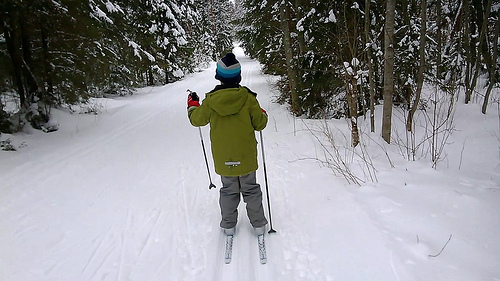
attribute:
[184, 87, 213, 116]
glove — red, protective gloves, on the left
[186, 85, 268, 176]
olive greencoat — green 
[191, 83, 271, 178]
jersey — green 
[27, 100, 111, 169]
snow — covering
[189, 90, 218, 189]
pole — black 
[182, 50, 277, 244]
young person — young 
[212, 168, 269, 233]
grey snowpants — grey 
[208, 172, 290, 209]
boy's pants — gray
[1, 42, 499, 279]
snow — white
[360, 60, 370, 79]
leaves — green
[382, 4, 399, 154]
tree trunk — straight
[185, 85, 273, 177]
jacket — green 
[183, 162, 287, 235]
pants — grey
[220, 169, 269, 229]
pants —  gray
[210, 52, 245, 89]
hat — grey , blue 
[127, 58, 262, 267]
snow passage — long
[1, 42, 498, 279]
ground — covered